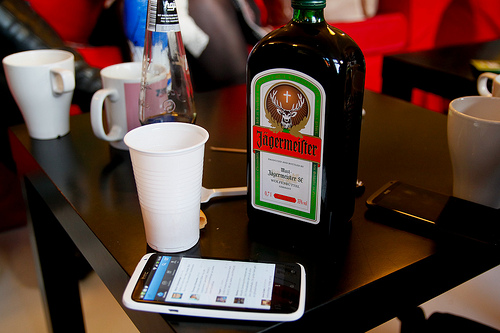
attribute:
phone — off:
[117, 238, 283, 325]